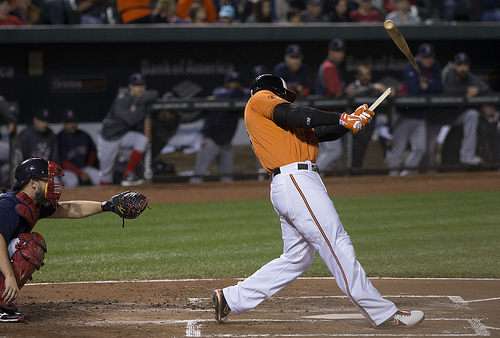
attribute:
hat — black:
[249, 73, 293, 98]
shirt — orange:
[243, 89, 320, 173]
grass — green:
[67, 225, 237, 273]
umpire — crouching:
[0, 159, 154, 323]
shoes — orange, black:
[189, 284, 441, 334]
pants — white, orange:
[222, 161, 398, 328]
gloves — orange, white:
[330, 101, 387, 148]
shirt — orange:
[241, 87, 340, 171]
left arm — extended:
[42, 181, 155, 231]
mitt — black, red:
[108, 187, 158, 227]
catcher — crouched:
[5, 148, 158, 329]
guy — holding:
[212, 65, 438, 333]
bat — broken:
[330, 76, 423, 133]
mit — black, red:
[100, 190, 154, 220]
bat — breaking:
[354, 88, 392, 132]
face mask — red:
[47, 160, 64, 214]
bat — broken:
[348, 63, 406, 146]